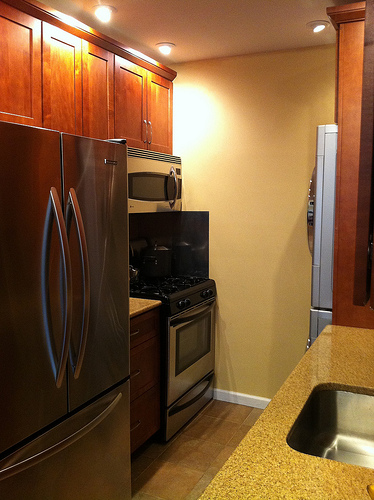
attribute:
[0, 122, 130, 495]
refrigerator — steel, large, black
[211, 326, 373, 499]
counter — granite, tan, mustard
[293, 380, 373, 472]
sink — empty, metal, steel, steal, deep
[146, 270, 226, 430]
oven — steel, black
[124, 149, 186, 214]
microwave — steel, metal, gray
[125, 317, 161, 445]
drawers — small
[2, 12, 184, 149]
cabinets — wood, cherry, brown, wooden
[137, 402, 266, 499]
floor — granite, brown, tiled, tile, gray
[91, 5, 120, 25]
light — small, on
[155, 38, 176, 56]
light — small, on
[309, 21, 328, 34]
light — small, on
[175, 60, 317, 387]
wall — light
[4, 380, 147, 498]
freezer — drawer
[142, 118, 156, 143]
handles — silver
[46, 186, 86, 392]
handles — steel, steal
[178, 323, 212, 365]
window — glass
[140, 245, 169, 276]
pot — black, large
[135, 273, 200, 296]
stove — gas, black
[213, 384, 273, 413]
baseboard — white